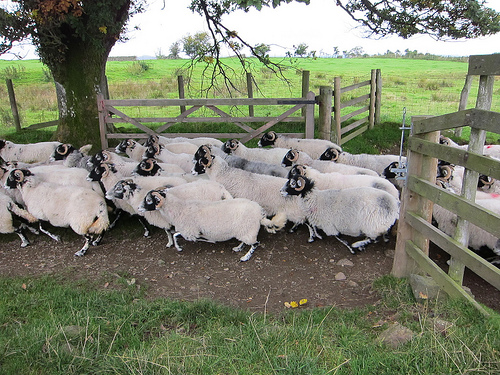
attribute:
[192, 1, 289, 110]
branches — hanging down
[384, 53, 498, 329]
fence — wood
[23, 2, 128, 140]
tree trunk — thick 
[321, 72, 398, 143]
gate — opened, wooden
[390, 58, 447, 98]
field — green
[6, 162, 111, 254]
sheep — white, horned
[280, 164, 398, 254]
sheep — horned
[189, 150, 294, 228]
sheep — horned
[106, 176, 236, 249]
sheep — horned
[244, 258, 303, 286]
dirt — brown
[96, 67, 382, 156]
fence — brown, wooden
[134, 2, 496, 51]
sky — bright , grey 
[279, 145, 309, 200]
faces — black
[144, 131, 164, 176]
faces — black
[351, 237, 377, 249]
leg — white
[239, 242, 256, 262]
leg — white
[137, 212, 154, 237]
leg — white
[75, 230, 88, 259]
leg — white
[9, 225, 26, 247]
leg — white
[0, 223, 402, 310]
trail — dirt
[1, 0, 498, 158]
tree — large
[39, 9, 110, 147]
trunk — green, brown, tree, largest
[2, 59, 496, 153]
grass — green, bright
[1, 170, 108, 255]
ram — white 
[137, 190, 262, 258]
sheep — horned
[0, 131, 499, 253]
rams — running away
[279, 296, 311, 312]
flowers — yellow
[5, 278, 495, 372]
grass — tall, green, short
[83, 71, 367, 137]
posts — brown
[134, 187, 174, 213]
horns — tan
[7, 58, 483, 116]
pasture — green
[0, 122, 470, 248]
sheep — white, herd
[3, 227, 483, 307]
dirt — brown